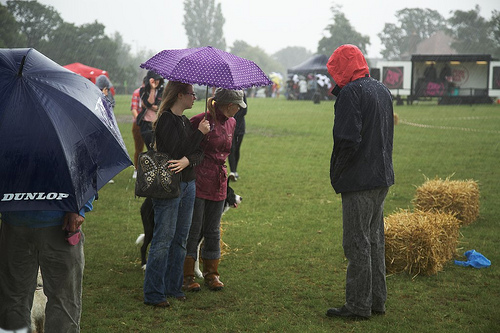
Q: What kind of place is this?
A: It is a field.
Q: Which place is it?
A: It is a field.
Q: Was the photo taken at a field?
A: Yes, it was taken in a field.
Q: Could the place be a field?
A: Yes, it is a field.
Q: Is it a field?
A: Yes, it is a field.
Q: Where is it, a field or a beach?
A: It is a field.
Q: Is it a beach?
A: No, it is a field.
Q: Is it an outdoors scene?
A: Yes, it is outdoors.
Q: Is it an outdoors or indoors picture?
A: It is outdoors.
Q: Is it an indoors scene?
A: No, it is outdoors.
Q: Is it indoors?
A: No, it is outdoors.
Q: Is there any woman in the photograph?
A: Yes, there is a woman.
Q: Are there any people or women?
A: Yes, there is a woman.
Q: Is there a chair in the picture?
A: No, there are no chairs.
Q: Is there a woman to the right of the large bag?
A: Yes, there is a woman to the right of the handbag.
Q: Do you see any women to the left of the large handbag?
A: No, the woman is to the right of the handbag.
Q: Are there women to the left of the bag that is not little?
A: No, the woman is to the right of the handbag.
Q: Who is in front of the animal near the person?
A: The woman is in front of the dog.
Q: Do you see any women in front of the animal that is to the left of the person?
A: Yes, there is a woman in front of the dog.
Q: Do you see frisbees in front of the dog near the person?
A: No, there is a woman in front of the dog.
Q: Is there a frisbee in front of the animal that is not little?
A: No, there is a woman in front of the dog.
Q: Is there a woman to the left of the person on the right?
A: Yes, there is a woman to the left of the person.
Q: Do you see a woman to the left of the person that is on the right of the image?
A: Yes, there is a woman to the left of the person.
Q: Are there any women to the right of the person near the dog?
A: No, the woman is to the left of the person.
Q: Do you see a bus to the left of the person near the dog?
A: No, there is a woman to the left of the person.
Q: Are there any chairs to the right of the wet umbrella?
A: No, there is a woman to the right of the umbrella.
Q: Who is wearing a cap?
A: The woman is wearing a cap.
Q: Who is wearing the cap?
A: The woman is wearing a cap.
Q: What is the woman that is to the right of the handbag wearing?
A: The woman is wearing a cap.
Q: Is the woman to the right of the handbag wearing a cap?
A: Yes, the woman is wearing a cap.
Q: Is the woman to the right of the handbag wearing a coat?
A: No, the woman is wearing a cap.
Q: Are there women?
A: Yes, there is a woman.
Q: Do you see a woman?
A: Yes, there is a woman.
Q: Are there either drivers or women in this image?
A: Yes, there is a woman.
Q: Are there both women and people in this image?
A: Yes, there are both a woman and people.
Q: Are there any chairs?
A: No, there are no chairs.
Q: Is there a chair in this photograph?
A: No, there are no chairs.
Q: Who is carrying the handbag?
A: The woman is carrying the handbag.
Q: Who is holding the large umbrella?
A: The woman is holding the umbrella.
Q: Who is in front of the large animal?
A: The woman is in front of the dog.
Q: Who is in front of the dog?
A: The woman is in front of the dog.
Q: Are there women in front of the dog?
A: Yes, there is a woman in front of the dog.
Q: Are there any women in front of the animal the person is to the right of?
A: Yes, there is a woman in front of the dog.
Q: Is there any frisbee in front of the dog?
A: No, there is a woman in front of the dog.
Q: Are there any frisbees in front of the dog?
A: No, there is a woman in front of the dog.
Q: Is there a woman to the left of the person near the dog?
A: Yes, there is a woman to the left of the person.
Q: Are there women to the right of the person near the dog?
A: No, the woman is to the left of the person.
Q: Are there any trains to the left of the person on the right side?
A: No, there is a woman to the left of the person.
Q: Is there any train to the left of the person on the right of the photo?
A: No, there is a woman to the left of the person.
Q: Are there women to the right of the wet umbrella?
A: Yes, there is a woman to the right of the umbrella.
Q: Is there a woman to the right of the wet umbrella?
A: Yes, there is a woman to the right of the umbrella.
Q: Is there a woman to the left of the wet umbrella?
A: No, the woman is to the right of the umbrella.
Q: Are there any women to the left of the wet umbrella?
A: No, the woman is to the right of the umbrella.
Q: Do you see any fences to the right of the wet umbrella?
A: No, there is a woman to the right of the umbrella.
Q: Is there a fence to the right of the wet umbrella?
A: No, there is a woman to the right of the umbrella.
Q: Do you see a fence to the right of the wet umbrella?
A: No, there is a woman to the right of the umbrella.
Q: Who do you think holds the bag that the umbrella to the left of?
A: The woman holds the handbag.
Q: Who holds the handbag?
A: The woman holds the handbag.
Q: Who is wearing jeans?
A: The woman is wearing jeans.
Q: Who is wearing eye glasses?
A: The woman is wearing eye glasses.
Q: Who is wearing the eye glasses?
A: The woman is wearing eye glasses.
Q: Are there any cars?
A: No, there are no cars.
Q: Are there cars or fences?
A: No, there are no cars or fences.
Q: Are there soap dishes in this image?
A: No, there are no soap dishes.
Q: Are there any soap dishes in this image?
A: No, there are no soap dishes.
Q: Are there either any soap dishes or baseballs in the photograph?
A: No, there are no soap dishes or baseballs.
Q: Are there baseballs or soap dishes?
A: No, there are no soap dishes or baseballs.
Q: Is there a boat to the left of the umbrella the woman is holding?
A: No, there is a tent to the left of the umbrella.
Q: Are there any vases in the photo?
A: No, there are no vases.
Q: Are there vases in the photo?
A: No, there are no vases.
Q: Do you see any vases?
A: No, there are no vases.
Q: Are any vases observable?
A: No, there are no vases.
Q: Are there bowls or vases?
A: No, there are no vases or bowls.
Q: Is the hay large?
A: Yes, the hay is large.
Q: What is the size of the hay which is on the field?
A: The hay is large.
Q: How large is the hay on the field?
A: The hay is large.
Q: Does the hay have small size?
A: No, the hay is large.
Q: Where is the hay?
A: The hay is on the field.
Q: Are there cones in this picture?
A: No, there are no cones.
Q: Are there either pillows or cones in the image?
A: No, there are no cones or pillows.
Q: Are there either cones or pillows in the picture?
A: No, there are no cones or pillows.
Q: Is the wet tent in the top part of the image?
A: Yes, the tent is in the top of the image.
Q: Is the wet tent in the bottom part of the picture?
A: No, the tent is in the top of the image.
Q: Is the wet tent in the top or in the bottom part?
A: The tent is in the top of the image.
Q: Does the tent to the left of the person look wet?
A: Yes, the tent is wet.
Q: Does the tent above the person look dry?
A: No, the tent is wet.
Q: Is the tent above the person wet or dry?
A: The tent is wet.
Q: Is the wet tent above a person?
A: Yes, the tent is above a person.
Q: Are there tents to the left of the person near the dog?
A: Yes, there is a tent to the left of the person.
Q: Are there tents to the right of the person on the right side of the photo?
A: No, the tent is to the left of the person.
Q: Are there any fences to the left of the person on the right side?
A: No, there is a tent to the left of the person.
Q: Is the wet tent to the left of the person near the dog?
A: Yes, the tent is to the left of the person.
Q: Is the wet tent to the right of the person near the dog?
A: No, the tent is to the left of the person.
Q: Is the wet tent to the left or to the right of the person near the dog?
A: The tent is to the left of the person.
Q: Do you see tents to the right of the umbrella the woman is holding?
A: Yes, there is a tent to the right of the umbrella.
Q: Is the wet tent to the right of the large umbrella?
A: Yes, the tent is to the right of the umbrella.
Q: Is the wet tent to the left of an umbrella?
A: No, the tent is to the right of an umbrella.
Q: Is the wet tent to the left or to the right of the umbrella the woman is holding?
A: The tent is to the right of the umbrella.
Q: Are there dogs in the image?
A: Yes, there is a dog.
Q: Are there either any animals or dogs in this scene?
A: Yes, there is a dog.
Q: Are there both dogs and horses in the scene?
A: No, there is a dog but no horses.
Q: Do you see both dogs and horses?
A: No, there is a dog but no horses.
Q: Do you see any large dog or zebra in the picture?
A: Yes, there is a large dog.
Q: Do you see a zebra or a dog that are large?
A: Yes, the dog is large.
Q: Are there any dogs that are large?
A: Yes, there is a large dog.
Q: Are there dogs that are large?
A: Yes, there is a dog that is large.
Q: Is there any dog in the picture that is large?
A: Yes, there is a dog that is large.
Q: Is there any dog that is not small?
A: Yes, there is a large dog.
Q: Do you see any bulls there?
A: No, there are no bulls.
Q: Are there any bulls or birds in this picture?
A: No, there are no bulls or birds.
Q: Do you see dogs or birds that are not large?
A: No, there is a dog but it is large.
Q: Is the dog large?
A: Yes, the dog is large.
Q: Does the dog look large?
A: Yes, the dog is large.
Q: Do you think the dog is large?
A: Yes, the dog is large.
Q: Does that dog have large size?
A: Yes, the dog is large.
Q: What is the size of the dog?
A: The dog is large.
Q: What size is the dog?
A: The dog is large.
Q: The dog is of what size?
A: The dog is large.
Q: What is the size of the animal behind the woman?
A: The dog is large.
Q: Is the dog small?
A: No, the dog is large.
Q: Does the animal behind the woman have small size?
A: No, the dog is large.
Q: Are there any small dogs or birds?
A: No, there is a dog but it is large.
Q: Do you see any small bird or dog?
A: No, there is a dog but it is large.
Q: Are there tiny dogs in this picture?
A: No, there is a dog but it is large.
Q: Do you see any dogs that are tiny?
A: No, there is a dog but it is large.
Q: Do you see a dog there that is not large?
A: No, there is a dog but it is large.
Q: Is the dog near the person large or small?
A: The dog is large.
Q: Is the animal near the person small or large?
A: The dog is large.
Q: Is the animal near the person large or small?
A: The dog is large.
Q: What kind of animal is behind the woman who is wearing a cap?
A: The animal is a dog.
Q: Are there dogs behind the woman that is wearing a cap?
A: Yes, there is a dog behind the woman.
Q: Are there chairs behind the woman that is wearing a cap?
A: No, there is a dog behind the woman.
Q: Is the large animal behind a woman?
A: Yes, the dog is behind a woman.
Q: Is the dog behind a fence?
A: No, the dog is behind a woman.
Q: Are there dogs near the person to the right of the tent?
A: Yes, there is a dog near the person.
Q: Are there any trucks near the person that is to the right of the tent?
A: No, there is a dog near the person.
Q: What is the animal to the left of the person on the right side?
A: The animal is a dog.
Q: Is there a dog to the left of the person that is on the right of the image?
A: Yes, there is a dog to the left of the person.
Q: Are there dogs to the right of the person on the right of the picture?
A: No, the dog is to the left of the person.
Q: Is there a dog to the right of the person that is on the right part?
A: No, the dog is to the left of the person.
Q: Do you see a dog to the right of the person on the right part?
A: No, the dog is to the left of the person.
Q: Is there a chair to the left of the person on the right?
A: No, there is a dog to the left of the person.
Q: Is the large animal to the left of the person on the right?
A: Yes, the dog is to the left of the person.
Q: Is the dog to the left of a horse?
A: No, the dog is to the left of the person.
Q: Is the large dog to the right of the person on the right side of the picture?
A: No, the dog is to the left of the person.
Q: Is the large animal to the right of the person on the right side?
A: No, the dog is to the left of the person.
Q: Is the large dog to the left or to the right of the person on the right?
A: The dog is to the left of the person.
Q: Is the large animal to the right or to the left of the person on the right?
A: The dog is to the left of the person.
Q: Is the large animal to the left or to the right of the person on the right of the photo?
A: The dog is to the left of the person.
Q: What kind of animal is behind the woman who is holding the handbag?
A: The animal is a dog.